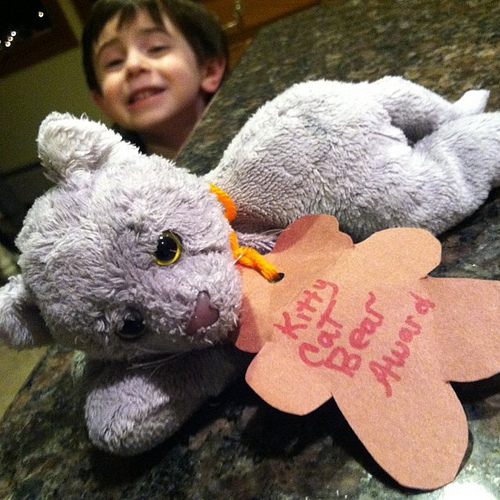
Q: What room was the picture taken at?
A: It was taken at the kitchen.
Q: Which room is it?
A: It is a kitchen.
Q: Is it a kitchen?
A: Yes, it is a kitchen.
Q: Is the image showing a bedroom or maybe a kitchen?
A: It is showing a kitchen.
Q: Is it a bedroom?
A: No, it is a kitchen.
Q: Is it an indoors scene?
A: Yes, it is indoors.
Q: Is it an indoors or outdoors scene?
A: It is indoors.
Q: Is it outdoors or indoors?
A: It is indoors.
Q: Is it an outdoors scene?
A: No, it is indoors.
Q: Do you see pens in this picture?
A: No, there are no pens.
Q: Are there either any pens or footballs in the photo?
A: No, there are no pens or footballs.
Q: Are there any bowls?
A: No, there are no bowls.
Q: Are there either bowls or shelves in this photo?
A: No, there are no bowls or shelves.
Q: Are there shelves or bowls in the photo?
A: No, there are no bowls or shelves.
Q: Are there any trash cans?
A: No, there are no trash cans.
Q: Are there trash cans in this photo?
A: No, there are no trash cans.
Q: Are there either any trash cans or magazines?
A: No, there are no trash cans or magazines.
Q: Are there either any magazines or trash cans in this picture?
A: No, there are no trash cans or magazines.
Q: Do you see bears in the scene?
A: Yes, there is a bear.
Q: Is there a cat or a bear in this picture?
A: Yes, there is a bear.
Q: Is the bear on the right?
A: Yes, the bear is on the right of the image.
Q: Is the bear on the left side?
A: No, the bear is on the right of the image.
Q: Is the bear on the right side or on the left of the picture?
A: The bear is on the right of the image.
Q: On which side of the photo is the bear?
A: The bear is on the right of the image.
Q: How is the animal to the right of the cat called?
A: The animal is a bear.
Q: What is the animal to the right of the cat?
A: The animal is a bear.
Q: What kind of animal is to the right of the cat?
A: The animal is a bear.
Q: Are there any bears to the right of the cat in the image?
A: Yes, there is a bear to the right of the cat.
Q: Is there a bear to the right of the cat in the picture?
A: Yes, there is a bear to the right of the cat.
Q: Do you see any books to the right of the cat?
A: No, there is a bear to the right of the cat.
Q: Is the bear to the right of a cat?
A: Yes, the bear is to the right of a cat.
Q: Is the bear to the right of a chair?
A: No, the bear is to the right of a cat.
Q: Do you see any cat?
A: Yes, there is a cat.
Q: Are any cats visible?
A: Yes, there is a cat.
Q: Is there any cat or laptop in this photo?
A: Yes, there is a cat.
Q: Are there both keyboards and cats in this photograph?
A: No, there is a cat but no keyboards.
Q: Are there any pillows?
A: No, there are no pillows.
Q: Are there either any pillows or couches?
A: No, there are no pillows or couches.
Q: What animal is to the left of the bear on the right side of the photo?
A: The animal is a cat.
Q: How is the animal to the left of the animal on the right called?
A: The animal is a cat.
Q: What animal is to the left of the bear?
A: The animal is a cat.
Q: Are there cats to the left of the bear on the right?
A: Yes, there is a cat to the left of the bear.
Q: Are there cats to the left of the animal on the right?
A: Yes, there is a cat to the left of the bear.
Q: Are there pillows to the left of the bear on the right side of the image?
A: No, there is a cat to the left of the bear.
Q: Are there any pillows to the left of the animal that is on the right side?
A: No, there is a cat to the left of the bear.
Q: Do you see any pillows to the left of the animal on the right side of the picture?
A: No, there is a cat to the left of the bear.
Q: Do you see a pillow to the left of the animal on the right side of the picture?
A: No, there is a cat to the left of the bear.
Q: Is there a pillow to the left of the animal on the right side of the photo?
A: No, there is a cat to the left of the bear.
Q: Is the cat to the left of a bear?
A: Yes, the cat is to the left of a bear.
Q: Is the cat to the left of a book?
A: No, the cat is to the left of a bear.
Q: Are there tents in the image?
A: No, there are no tents.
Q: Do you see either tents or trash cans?
A: No, there are no tents or trash cans.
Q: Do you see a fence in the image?
A: No, there are no fences.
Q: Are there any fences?
A: No, there are no fences.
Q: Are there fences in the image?
A: No, there are no fences.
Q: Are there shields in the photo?
A: No, there are no shields.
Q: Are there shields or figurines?
A: No, there are no shields or figurines.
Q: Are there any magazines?
A: No, there are no magazines.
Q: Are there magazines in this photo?
A: No, there are no magazines.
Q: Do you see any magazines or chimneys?
A: No, there are no magazines or chimneys.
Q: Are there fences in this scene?
A: No, there are no fences.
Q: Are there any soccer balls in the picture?
A: No, there are no soccer balls.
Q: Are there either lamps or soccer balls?
A: No, there are no soccer balls or lamps.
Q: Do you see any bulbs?
A: No, there are no bulbs.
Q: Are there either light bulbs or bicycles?
A: No, there are no light bulbs or bicycles.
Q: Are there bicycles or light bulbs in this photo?
A: No, there are no light bulbs or bicycles.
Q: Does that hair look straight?
A: Yes, the hair is straight.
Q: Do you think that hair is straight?
A: Yes, the hair is straight.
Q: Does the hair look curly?
A: No, the hair is straight.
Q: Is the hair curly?
A: No, the hair is straight.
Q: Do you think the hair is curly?
A: No, the hair is straight.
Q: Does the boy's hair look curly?
A: No, the hair is straight.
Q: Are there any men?
A: No, there are no men.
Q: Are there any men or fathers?
A: No, there are no men or fathers.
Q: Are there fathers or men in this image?
A: No, there are no men or fathers.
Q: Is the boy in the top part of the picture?
A: Yes, the boy is in the top of the image.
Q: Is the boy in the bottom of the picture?
A: No, the boy is in the top of the image.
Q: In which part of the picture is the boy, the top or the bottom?
A: The boy is in the top of the image.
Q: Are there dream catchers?
A: No, there are no dream catchers.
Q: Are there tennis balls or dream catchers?
A: No, there are no dream catchers or tennis balls.